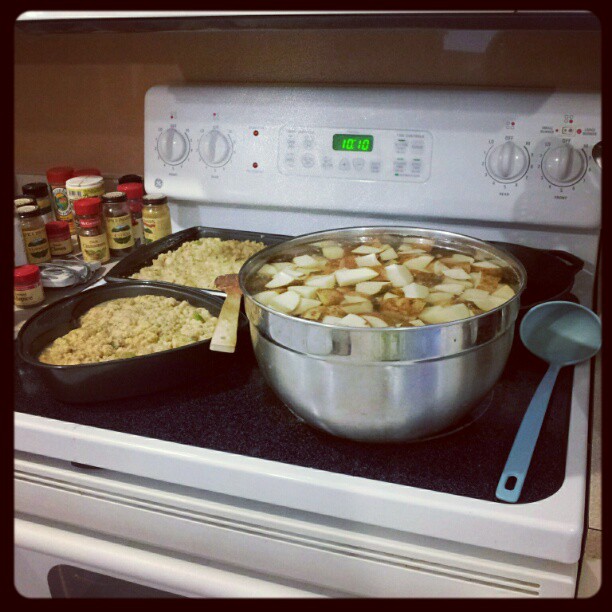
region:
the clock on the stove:
[333, 132, 370, 149]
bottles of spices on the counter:
[15, 170, 161, 293]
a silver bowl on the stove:
[249, 230, 517, 431]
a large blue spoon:
[498, 293, 600, 508]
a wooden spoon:
[211, 273, 245, 350]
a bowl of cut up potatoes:
[251, 237, 519, 442]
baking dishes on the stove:
[22, 223, 272, 396]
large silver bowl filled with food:
[230, 221, 530, 455]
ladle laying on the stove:
[500, 282, 606, 510]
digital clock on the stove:
[332, 126, 374, 157]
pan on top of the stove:
[21, 265, 255, 399]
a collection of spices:
[8, 151, 178, 269]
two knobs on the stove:
[481, 120, 605, 212]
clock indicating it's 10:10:
[325, 129, 372, 152]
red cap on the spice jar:
[75, 193, 99, 217]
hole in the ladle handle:
[500, 472, 522, 500]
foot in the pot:
[318, 298, 350, 314]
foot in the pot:
[460, 286, 490, 299]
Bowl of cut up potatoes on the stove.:
[257, 223, 529, 439]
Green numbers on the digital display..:
[310, 117, 387, 163]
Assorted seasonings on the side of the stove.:
[8, 156, 160, 271]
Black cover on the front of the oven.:
[33, 560, 115, 607]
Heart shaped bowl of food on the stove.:
[31, 261, 200, 372]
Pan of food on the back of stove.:
[143, 226, 279, 297]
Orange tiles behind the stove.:
[57, 51, 119, 129]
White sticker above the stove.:
[421, 27, 529, 68]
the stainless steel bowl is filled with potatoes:
[259, 230, 523, 438]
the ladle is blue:
[501, 300, 594, 521]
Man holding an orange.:
[374, 278, 375, 319]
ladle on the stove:
[496, 273, 605, 539]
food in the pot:
[235, 225, 513, 356]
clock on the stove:
[315, 125, 380, 167]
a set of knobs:
[137, 113, 241, 188]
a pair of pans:
[18, 220, 262, 406]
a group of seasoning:
[18, 155, 168, 262]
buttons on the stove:
[261, 111, 439, 188]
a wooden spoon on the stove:
[192, 249, 248, 381]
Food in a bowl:
[273, 246, 492, 324]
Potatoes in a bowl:
[273, 235, 498, 321]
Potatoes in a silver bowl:
[294, 236, 482, 311]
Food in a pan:
[53, 291, 229, 359]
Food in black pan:
[32, 302, 217, 371]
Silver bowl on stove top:
[226, 206, 539, 449]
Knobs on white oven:
[163, 122, 246, 177]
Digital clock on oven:
[325, 128, 386, 155]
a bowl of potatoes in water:
[239, 222, 527, 444]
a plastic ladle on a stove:
[495, 300, 602, 505]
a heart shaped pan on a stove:
[17, 282, 246, 401]